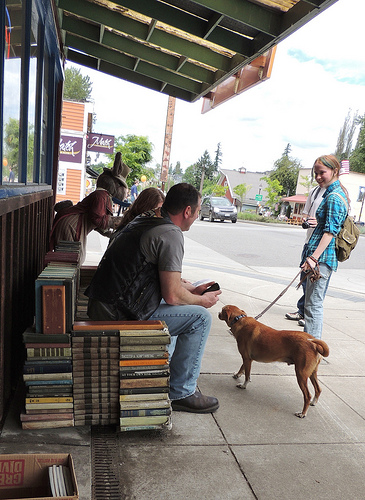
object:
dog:
[217, 303, 330, 420]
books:
[119, 335, 171, 345]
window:
[0, 0, 67, 201]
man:
[81, 178, 222, 418]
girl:
[298, 153, 352, 341]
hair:
[162, 181, 203, 218]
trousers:
[145, 298, 212, 402]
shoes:
[171, 388, 220, 414]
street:
[182, 212, 365, 272]